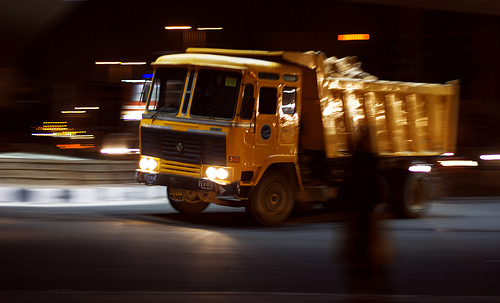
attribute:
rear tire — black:
[392, 165, 434, 220]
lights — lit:
[137, 157, 159, 170]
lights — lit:
[203, 164, 228, 184]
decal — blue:
[258, 125, 272, 140]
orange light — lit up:
[338, 30, 373, 42]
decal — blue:
[258, 120, 273, 140]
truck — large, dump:
[113, 31, 473, 235]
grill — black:
[141, 125, 223, 165]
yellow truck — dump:
[133, 45, 460, 228]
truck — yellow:
[128, 11, 473, 238]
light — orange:
[331, 26, 373, 50]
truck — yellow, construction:
[131, 37, 464, 224]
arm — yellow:
[243, 67, 256, 134]